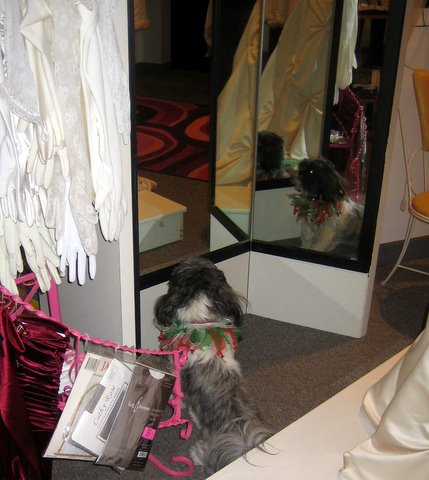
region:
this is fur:
[184, 269, 226, 367]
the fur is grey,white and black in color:
[185, 262, 237, 410]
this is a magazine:
[53, 354, 160, 466]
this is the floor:
[256, 327, 320, 404]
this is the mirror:
[130, 90, 335, 260]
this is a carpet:
[146, 107, 193, 163]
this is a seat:
[383, 102, 427, 289]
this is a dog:
[277, 149, 359, 251]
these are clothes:
[0, 0, 119, 234]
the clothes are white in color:
[3, 41, 120, 234]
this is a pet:
[173, 267, 242, 458]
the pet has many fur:
[203, 382, 244, 425]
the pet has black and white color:
[178, 288, 214, 313]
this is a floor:
[259, 332, 289, 371]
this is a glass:
[280, 54, 326, 111]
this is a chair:
[408, 194, 423, 279]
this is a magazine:
[76, 375, 107, 425]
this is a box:
[144, 206, 177, 239]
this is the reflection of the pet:
[292, 157, 355, 247]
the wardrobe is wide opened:
[132, 18, 364, 244]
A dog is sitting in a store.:
[141, 250, 282, 476]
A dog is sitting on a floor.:
[141, 242, 286, 475]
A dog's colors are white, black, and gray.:
[138, 251, 297, 475]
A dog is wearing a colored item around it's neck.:
[143, 306, 249, 359]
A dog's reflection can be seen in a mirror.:
[279, 146, 368, 269]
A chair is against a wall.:
[368, 57, 427, 298]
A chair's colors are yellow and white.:
[368, 52, 426, 301]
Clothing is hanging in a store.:
[0, 0, 142, 303]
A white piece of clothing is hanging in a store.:
[72, 0, 149, 251]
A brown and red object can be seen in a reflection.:
[131, 79, 231, 213]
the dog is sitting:
[147, 244, 259, 440]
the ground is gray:
[253, 345, 308, 396]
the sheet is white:
[341, 357, 415, 462]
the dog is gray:
[141, 237, 259, 454]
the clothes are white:
[11, 9, 123, 276]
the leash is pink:
[152, 324, 196, 439]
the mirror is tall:
[131, 16, 251, 289]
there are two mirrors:
[123, 11, 372, 299]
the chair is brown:
[399, 153, 427, 232]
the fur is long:
[182, 327, 264, 448]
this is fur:
[179, 269, 229, 307]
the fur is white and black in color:
[179, 270, 250, 414]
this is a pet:
[181, 263, 244, 472]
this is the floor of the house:
[266, 329, 324, 394]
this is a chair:
[391, 137, 428, 284]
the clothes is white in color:
[7, 51, 78, 279]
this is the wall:
[385, 174, 403, 235]